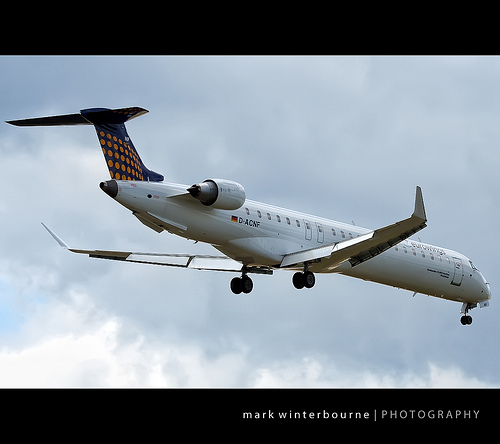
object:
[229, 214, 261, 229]
emblem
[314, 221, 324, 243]
door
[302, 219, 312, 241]
door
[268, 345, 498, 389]
clouds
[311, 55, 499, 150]
sky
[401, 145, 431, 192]
ground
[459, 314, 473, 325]
front wheel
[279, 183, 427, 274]
wing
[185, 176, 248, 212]
engine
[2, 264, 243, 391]
clouds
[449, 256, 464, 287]
hatch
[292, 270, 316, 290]
wheels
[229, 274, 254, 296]
wheels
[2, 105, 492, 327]
airplane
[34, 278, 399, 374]
sky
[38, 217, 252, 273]
wing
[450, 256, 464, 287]
door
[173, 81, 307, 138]
sky